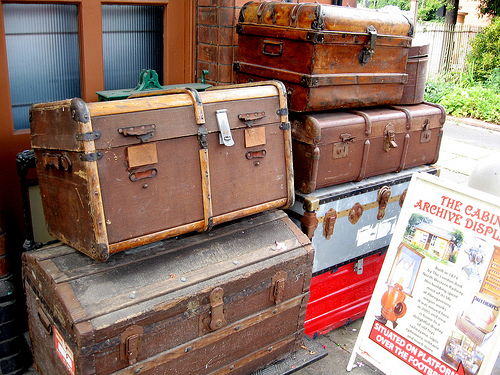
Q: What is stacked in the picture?
A: Luggage.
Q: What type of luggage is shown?
A: Antique trunks.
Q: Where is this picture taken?
A: A museum.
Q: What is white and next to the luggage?
A: A display sign.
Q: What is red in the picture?
A: The bottom right trunk.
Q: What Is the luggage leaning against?
A: A door.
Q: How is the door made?
A: Of glass and wood.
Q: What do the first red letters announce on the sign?
A: The Cabin Archive Display.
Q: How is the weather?
A: Clear.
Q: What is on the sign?
A: Words.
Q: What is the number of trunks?
A: Six.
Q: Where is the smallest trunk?
A: On top of three trunks.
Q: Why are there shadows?
A: The day is sunny.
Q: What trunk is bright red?
A: The bottom one.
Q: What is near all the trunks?
A: A billboard.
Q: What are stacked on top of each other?
A: Trunks.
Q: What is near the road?
A: Green plants.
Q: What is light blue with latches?
A: A pale blue trunk.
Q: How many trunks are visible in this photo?
A: Seven.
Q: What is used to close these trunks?
A: Latches.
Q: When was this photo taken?
A: Outside, during the daytime.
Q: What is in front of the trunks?
A: A folding sign.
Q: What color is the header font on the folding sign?
A: Red.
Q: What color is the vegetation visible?
A: Green.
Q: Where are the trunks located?
A: In front of a building.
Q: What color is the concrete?
A: Gray.